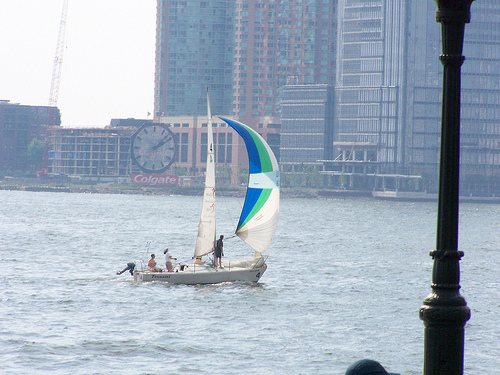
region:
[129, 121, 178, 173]
one round clock with black hands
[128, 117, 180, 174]
round clock with white face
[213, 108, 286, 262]
one white blue and green sail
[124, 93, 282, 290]
one white sailboat in water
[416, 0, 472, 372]
one black metal lamp post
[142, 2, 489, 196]
view of several skyscrapers by body of water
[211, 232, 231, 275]
one man wearing dark shorts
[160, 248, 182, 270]
one woman wearing white short sleeved shirt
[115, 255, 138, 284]
one dark metal boat engine propped up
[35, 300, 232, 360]
view of choppy gray water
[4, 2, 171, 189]
large crane over buildings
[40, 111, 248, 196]
large clock on face of building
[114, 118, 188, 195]
Red sign under large clock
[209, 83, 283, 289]
Blue, White, and Green sail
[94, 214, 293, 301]
white boat on huge body of water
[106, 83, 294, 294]
white male steering white boat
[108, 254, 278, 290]
Black engine behind white boat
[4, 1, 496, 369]
Black pole towering over boat in the background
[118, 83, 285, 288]
completely white sail on white boat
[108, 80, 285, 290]
three Caucasians on sailing on white boat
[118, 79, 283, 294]
Three people on a sailboat on a waterway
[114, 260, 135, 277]
A black motor on the back of the sailboat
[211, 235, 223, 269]
A man standing on the sailboat wearing a shirt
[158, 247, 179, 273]
A woman standing on the sailboat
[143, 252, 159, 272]
A shirtless man standing on the sailboat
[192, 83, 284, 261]
Two sails puffed out with wind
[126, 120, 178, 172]
A large clock with roman numerals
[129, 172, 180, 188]
A large Colgate advertisement sign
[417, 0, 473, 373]
A large black metal post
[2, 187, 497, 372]
A calm waterway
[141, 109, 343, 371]
a boat in the water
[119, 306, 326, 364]
a body of water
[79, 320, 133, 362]
a body of blue water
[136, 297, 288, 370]
a body of water that is blue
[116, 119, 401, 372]
a sail boat in the water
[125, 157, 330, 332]
people on a boat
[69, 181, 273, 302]
people on a sailboat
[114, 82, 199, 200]
a large clock outside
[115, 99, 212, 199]
a large outside clock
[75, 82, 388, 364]
a clock that is outside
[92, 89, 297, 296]
A sail boat on a river